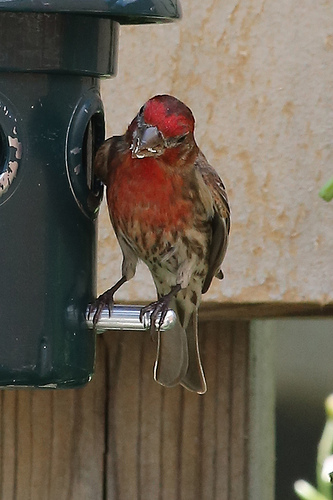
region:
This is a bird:
[82, 78, 264, 450]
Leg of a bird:
[137, 248, 203, 350]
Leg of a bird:
[79, 210, 133, 352]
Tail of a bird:
[163, 242, 238, 414]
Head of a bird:
[120, 89, 211, 165]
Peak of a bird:
[132, 127, 164, 166]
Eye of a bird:
[172, 127, 190, 151]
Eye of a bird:
[133, 98, 152, 122]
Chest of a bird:
[118, 155, 180, 241]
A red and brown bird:
[93, 81, 247, 418]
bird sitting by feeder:
[87, 91, 228, 390]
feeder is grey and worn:
[5, 4, 184, 388]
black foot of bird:
[85, 271, 125, 322]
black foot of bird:
[138, 292, 175, 327]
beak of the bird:
[130, 135, 158, 154]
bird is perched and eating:
[91, 97, 232, 391]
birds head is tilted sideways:
[78, 92, 229, 395]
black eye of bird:
[177, 131, 186, 142]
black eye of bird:
[139, 106, 146, 115]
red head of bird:
[141, 94, 191, 135]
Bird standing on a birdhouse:
[94, 81, 220, 329]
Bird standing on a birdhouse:
[80, 268, 195, 354]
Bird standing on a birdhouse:
[75, 194, 221, 394]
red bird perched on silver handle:
[82, 89, 235, 392]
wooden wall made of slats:
[0, 320, 270, 497]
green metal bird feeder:
[4, 3, 210, 400]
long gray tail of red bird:
[147, 267, 211, 397]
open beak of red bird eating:
[129, 124, 170, 161]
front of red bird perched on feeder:
[108, 91, 209, 250]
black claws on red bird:
[84, 273, 186, 334]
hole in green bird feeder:
[64, 86, 122, 220]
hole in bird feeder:
[3, 94, 25, 197]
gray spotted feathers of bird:
[135, 218, 208, 325]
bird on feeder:
[93, 93, 226, 396]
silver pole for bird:
[91, 307, 170, 328]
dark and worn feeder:
[0, 2, 184, 387]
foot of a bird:
[138, 285, 181, 335]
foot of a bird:
[84, 284, 125, 325]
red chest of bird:
[112, 165, 190, 234]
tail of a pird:
[152, 296, 208, 395]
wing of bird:
[198, 172, 229, 289]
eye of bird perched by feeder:
[173, 133, 180, 142]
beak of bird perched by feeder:
[131, 128, 162, 151]